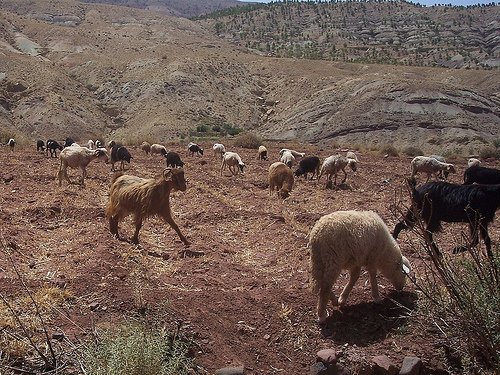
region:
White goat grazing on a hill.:
[307, 205, 411, 316]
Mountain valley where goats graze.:
[139, 120, 280, 150]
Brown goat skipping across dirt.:
[105, 163, 192, 248]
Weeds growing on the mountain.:
[68, 314, 190, 374]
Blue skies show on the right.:
[414, 0, 490, 9]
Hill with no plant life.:
[329, 68, 494, 140]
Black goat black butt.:
[393, 180, 494, 260]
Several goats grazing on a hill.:
[211, 143, 363, 200]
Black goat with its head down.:
[187, 141, 206, 156]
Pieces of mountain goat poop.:
[15, 236, 106, 318]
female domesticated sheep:
[293, 207, 434, 324]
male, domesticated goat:
[96, 145, 208, 272]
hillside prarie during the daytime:
[0, 89, 370, 359]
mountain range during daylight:
[69, 2, 495, 162]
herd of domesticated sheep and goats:
[2, 98, 484, 332]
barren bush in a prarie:
[378, 167, 498, 362]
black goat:
[386, 157, 498, 269]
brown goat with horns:
[78, 157, 202, 257]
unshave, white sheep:
[285, 196, 432, 333]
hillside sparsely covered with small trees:
[158, 1, 496, 82]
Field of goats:
[40, 124, 495, 317]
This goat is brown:
[100, 167, 204, 236]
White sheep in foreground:
[311, 180, 416, 321]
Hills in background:
[15, 13, 497, 135]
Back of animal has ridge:
[407, 170, 497, 200]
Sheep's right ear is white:
[399, 257, 414, 278]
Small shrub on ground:
[62, 315, 187, 373]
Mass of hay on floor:
[208, 201, 314, 278]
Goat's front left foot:
[173, 224, 197, 256]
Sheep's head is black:
[237, 160, 249, 177]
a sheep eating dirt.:
[301, 203, 422, 331]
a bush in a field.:
[54, 290, 226, 372]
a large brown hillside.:
[0, 0, 497, 160]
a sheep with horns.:
[97, 153, 209, 264]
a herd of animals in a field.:
[1, 110, 493, 310]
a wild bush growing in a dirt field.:
[41, 277, 214, 374]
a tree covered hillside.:
[187, 0, 497, 71]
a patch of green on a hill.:
[180, 114, 242, 143]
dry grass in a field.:
[273, 300, 303, 323]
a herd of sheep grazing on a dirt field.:
[12, 111, 498, 334]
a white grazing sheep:
[303, 201, 415, 321]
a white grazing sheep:
[220, 148, 247, 173]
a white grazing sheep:
[278, 145, 294, 170]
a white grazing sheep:
[256, 143, 270, 159]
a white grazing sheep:
[345, 148, 359, 173]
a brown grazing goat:
[263, 160, 294, 197]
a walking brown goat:
[105, 159, 193, 255]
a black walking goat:
[161, 148, 184, 170]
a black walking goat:
[109, 142, 132, 169]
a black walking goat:
[390, 169, 497, 257]